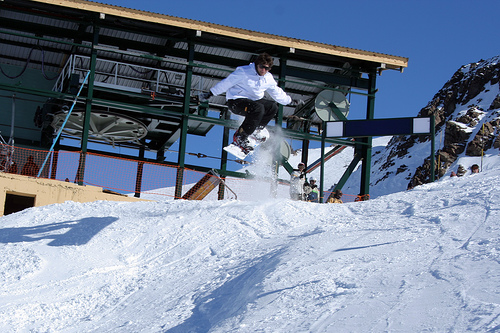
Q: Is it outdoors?
A: Yes, it is outdoors.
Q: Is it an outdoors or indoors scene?
A: It is outdoors.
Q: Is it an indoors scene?
A: No, it is outdoors.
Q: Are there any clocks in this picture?
A: No, there are no clocks.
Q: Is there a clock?
A: No, there are no clocks.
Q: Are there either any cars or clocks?
A: No, there are no clocks or cars.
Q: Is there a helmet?
A: No, there are no helmets.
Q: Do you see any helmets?
A: No, there are no helmets.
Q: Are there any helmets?
A: No, there are no helmets.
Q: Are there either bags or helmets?
A: No, there are no helmets or bags.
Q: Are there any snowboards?
A: Yes, there is a snowboard.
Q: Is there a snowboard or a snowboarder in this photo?
A: Yes, there is a snowboard.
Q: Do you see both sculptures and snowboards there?
A: No, there is a snowboard but no sculptures.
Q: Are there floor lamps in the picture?
A: No, there are no floor lamps.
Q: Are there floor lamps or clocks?
A: No, there are no floor lamps or clocks.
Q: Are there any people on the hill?
A: Yes, there is a person on the hill.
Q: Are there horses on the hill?
A: No, there is a person on the hill.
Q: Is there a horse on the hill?
A: No, there is a person on the hill.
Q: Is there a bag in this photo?
A: No, there are no bags.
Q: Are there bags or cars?
A: No, there are no bags or cars.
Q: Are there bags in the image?
A: No, there are no bags.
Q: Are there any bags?
A: No, there are no bags.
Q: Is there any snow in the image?
A: Yes, there is snow.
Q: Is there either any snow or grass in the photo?
A: Yes, there is snow.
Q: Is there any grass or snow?
A: Yes, there is snow.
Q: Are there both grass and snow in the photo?
A: No, there is snow but no grass.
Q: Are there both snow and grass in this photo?
A: No, there is snow but no grass.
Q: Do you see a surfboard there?
A: No, there are no surfboards.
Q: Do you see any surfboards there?
A: No, there are no surfboards.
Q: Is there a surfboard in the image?
A: No, there are no surfboards.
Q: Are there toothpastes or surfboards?
A: No, there are no surfboards or toothpastes.